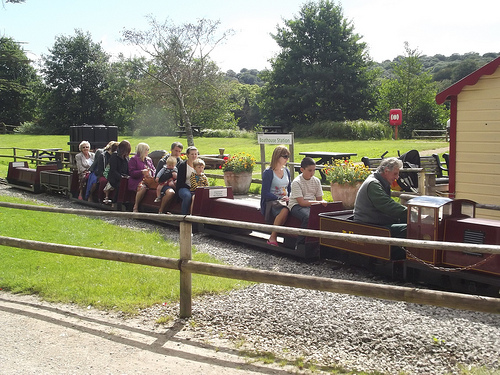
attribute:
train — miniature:
[8, 126, 499, 299]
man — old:
[353, 158, 420, 223]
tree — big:
[252, 2, 383, 120]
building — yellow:
[437, 56, 499, 223]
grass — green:
[3, 134, 499, 314]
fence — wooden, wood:
[2, 198, 497, 317]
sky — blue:
[2, 2, 495, 94]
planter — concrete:
[225, 169, 250, 192]